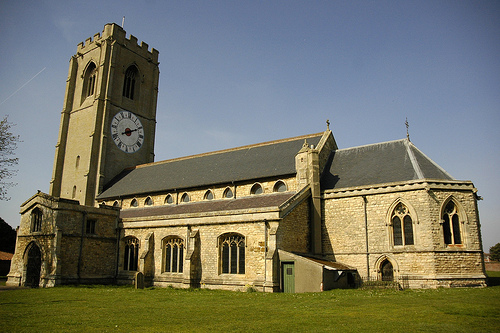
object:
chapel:
[48, 20, 160, 207]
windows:
[117, 59, 149, 101]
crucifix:
[324, 115, 338, 132]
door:
[275, 260, 303, 297]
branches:
[0, 107, 22, 206]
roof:
[75, 24, 162, 59]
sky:
[0, 4, 500, 208]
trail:
[5, 53, 56, 100]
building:
[0, 233, 23, 287]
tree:
[487, 238, 499, 262]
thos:
[370, 251, 400, 287]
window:
[81, 60, 100, 103]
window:
[118, 235, 141, 274]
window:
[162, 234, 185, 274]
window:
[216, 229, 247, 276]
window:
[389, 201, 413, 248]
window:
[441, 194, 466, 244]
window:
[273, 181, 291, 194]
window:
[249, 182, 264, 195]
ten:
[94, 178, 292, 212]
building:
[11, 17, 490, 290]